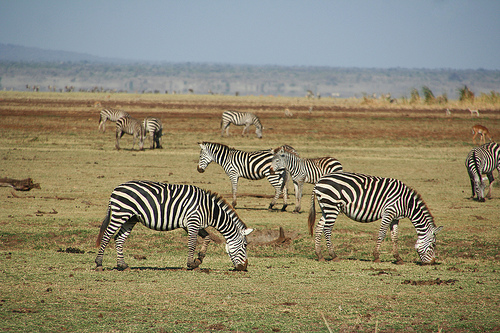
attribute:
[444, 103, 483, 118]
animals — light colored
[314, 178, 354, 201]
stripe — black, white, design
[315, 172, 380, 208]
design — crazy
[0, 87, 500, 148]
field — dry, arid, brown, muddy